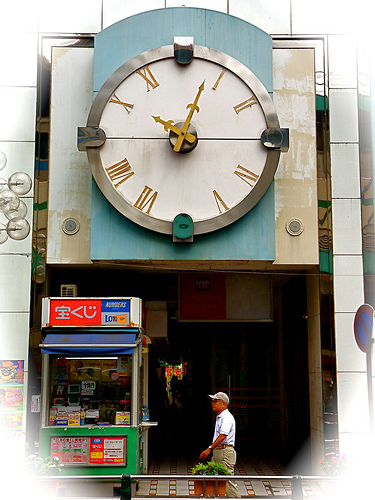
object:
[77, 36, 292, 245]
clock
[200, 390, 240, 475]
man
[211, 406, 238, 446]
shirt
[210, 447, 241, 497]
pants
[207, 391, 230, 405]
cap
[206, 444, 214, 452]
watch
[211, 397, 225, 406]
sunglasses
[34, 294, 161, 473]
vendor stand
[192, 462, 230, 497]
plants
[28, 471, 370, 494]
railing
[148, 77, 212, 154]
hands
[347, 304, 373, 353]
traffic sign